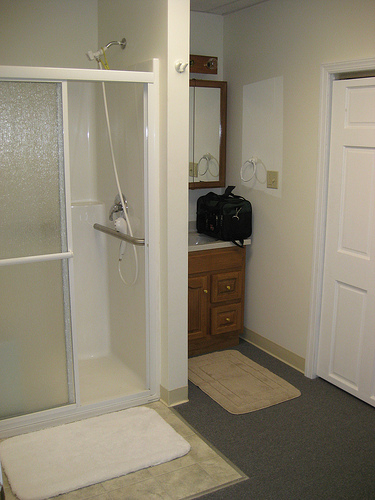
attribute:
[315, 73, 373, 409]
door — white, panel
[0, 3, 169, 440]
shower — large, white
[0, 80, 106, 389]
door — glass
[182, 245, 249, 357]
cabinets — brown, wooden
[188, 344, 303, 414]
mat — beige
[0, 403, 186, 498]
bath mat — white, fluffy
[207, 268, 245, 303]
drawer — round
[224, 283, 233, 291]
knob — gold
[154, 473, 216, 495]
tile — tan, ceramic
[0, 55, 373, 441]
frame — white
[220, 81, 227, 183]
border — brown, wooden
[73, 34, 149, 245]
shower — movable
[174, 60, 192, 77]
towel hanger — white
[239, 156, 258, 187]
rack — circular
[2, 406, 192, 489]
bath rug — white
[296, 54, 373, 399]
door — white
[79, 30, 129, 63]
shower — white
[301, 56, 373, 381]
door frame — white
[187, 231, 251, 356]
sink — white, brown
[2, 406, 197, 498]
rug — white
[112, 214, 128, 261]
shower head — white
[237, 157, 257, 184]
towel rod — circle, white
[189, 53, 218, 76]
fixture — brown, wooden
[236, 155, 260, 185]
towel rack — round, white